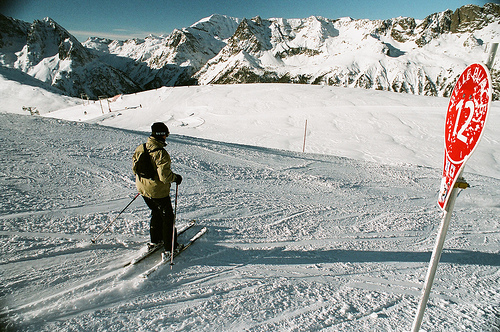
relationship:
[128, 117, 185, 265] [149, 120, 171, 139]
man wearing cap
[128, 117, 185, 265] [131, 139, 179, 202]
man wearing jacket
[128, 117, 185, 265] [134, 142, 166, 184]
man wearing backpack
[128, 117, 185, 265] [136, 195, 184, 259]
man wearing pants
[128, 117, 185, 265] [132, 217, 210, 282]
man on skis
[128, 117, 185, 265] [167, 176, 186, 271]
man holding ski poles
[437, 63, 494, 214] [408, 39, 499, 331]
sign on post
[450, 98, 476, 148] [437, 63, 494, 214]
number on sign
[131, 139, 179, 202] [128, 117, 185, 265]
jacket on man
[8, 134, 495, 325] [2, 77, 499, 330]
tracks are in snow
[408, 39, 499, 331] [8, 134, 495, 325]
post in snow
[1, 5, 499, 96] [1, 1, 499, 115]
mountains are in background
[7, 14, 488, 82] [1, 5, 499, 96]
snow on mountains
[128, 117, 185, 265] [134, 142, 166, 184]
man carrying backpack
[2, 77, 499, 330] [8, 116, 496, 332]
snow covers ground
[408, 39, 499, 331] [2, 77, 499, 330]
post in snow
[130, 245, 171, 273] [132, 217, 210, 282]
snow on skis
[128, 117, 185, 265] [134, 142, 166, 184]
man carries backpack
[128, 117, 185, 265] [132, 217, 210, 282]
man riding skis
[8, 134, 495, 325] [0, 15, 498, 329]
tracks are in snow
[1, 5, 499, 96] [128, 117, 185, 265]
mountains are ahead of man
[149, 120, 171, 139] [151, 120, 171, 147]
cap on head